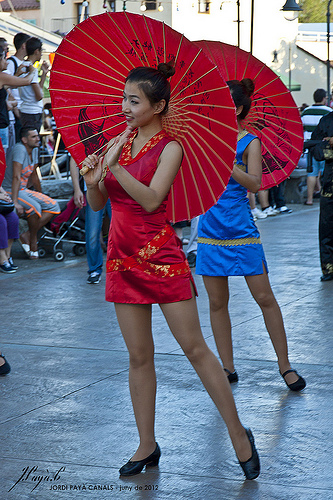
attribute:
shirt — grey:
[9, 140, 36, 184]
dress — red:
[94, 130, 201, 287]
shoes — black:
[96, 420, 296, 496]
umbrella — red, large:
[48, 9, 236, 222]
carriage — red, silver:
[32, 190, 91, 264]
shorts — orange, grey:
[10, 185, 58, 214]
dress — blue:
[188, 126, 270, 278]